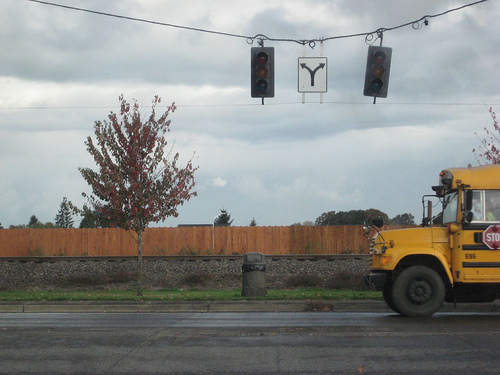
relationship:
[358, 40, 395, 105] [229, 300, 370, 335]
traffic light on road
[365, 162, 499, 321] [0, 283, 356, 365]
bus on road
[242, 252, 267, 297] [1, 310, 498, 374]
trash can on road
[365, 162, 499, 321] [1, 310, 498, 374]
bus on road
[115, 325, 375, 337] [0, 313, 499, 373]
dirt on street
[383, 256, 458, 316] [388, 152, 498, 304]
tire on bus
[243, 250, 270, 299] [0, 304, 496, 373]
trash can on road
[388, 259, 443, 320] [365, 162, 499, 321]
wheel on bus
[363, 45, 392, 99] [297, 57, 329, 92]
traffic light on sign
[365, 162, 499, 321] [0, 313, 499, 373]
bus on street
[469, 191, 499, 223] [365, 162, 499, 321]
window on bus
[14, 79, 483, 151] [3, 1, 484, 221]
clouds in sky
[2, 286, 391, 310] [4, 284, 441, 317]
grass growing on ground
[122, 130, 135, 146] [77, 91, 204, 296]
leaves on tree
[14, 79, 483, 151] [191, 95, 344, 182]
clouds in sky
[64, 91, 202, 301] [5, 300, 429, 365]
maple tree on road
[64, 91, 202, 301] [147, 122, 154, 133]
maple tree has pink leaves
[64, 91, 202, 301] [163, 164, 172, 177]
maple tree has pink leaves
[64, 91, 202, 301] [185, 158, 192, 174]
maple tree has pink leaves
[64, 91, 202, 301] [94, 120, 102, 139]
maple tree has pink leaves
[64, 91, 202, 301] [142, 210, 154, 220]
maple tree has pink leaves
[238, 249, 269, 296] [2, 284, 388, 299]
trash can on grass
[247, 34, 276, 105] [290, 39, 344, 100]
traffic light to left of sign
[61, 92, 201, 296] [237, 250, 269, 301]
tree near trash can